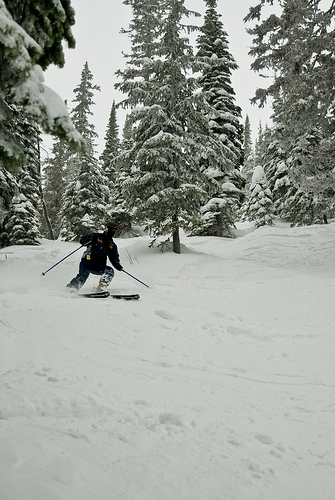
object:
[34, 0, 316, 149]
sky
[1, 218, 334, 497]
ski slope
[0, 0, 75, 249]
trees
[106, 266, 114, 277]
left knee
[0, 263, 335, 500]
snow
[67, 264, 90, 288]
right leg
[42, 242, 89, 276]
pole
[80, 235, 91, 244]
hand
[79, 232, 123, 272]
ski jacket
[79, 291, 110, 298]
skis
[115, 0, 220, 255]
tree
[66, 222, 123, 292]
man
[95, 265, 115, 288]
leg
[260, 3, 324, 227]
trees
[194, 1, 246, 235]
trees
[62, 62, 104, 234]
trees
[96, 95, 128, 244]
trees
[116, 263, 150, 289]
pole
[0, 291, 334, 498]
ground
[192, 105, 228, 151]
branch